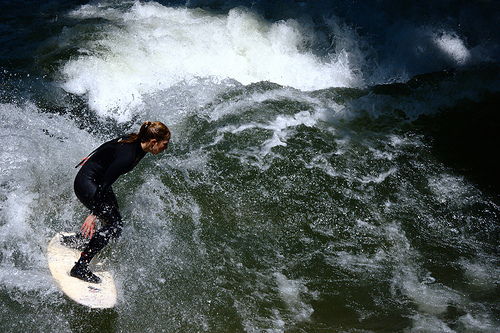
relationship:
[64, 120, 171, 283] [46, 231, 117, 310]
woman on a surfboard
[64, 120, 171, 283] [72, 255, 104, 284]
woman has a foot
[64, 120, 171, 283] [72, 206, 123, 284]
woman has a leg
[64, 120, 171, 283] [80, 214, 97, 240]
woman has a hand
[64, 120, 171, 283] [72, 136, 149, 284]
woman wearing a wetsuit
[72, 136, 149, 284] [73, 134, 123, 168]
wetsuit has a zipper string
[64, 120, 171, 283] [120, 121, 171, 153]
woman has a hair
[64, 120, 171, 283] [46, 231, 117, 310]
woman riding a surfboard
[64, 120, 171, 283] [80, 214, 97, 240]
woman with hand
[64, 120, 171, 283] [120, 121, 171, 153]
woman with a hair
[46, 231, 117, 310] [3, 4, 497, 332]
surfboard on water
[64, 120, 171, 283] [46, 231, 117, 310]
woman riding on a surfboard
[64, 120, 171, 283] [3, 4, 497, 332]
woman looking at water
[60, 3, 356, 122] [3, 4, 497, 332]
surf in water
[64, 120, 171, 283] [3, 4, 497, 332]
serfer on water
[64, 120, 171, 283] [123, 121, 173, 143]
woman has hair